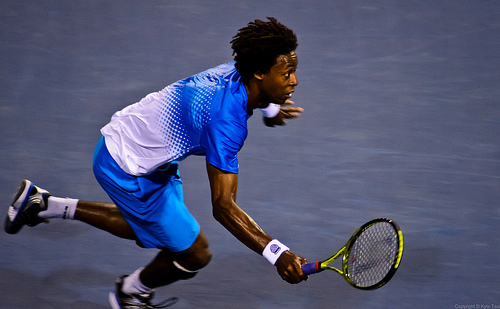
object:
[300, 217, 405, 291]
racket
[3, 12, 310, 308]
man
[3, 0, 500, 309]
tennis court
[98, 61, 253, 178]
shirt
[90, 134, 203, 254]
shorts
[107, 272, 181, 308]
shoes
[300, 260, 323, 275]
handle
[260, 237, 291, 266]
wristband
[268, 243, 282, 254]
symbol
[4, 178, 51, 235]
shoe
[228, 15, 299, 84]
hair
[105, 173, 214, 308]
legs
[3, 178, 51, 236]
foot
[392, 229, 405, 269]
line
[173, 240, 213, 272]
knee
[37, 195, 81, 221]
sock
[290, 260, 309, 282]
fingers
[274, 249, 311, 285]
hand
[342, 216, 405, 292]
head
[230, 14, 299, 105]
head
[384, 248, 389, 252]
strings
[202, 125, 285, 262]
arm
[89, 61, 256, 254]
outfit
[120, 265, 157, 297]
socks